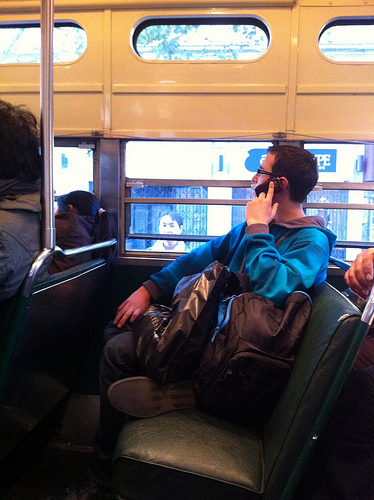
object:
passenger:
[80, 146, 336, 500]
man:
[0, 99, 51, 289]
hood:
[282, 215, 338, 258]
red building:
[238, 138, 334, 296]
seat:
[107, 275, 367, 499]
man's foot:
[105, 376, 202, 415]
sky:
[255, 176, 284, 197]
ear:
[278, 176, 288, 191]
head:
[58, 191, 100, 222]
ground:
[345, 82, 372, 113]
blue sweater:
[144, 217, 336, 309]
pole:
[39, 0, 57, 249]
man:
[77, 145, 337, 500]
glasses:
[257, 167, 282, 177]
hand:
[245, 181, 279, 228]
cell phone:
[255, 178, 284, 198]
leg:
[89, 332, 172, 490]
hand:
[114, 283, 151, 328]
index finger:
[266, 181, 275, 197]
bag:
[131, 259, 237, 382]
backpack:
[191, 287, 312, 427]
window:
[120, 135, 293, 261]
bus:
[0, 0, 373, 499]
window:
[134, 23, 270, 59]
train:
[2, 0, 373, 496]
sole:
[106, 377, 197, 419]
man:
[143, 211, 189, 253]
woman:
[41, 191, 119, 273]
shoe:
[106, 376, 198, 419]